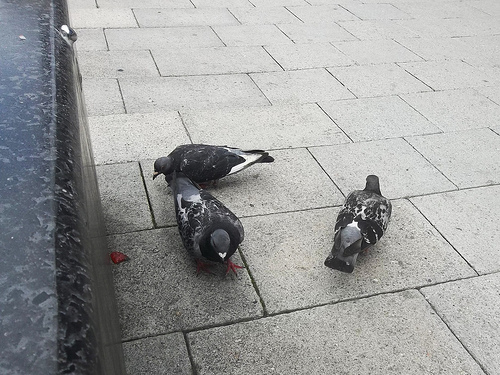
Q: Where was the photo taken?
A: It was taken at the sidewalk.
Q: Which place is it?
A: It is a sidewalk.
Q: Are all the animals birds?
A: No, there are both pigeons and birds.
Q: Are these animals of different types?
A: Yes, they are pigeons and birds.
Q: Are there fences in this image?
A: No, there are no fences.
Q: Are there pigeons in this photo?
A: Yes, there is a pigeon.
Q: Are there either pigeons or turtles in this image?
A: Yes, there is a pigeon.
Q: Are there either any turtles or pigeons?
A: Yes, there is a pigeon.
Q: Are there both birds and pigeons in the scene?
A: Yes, there are both a pigeon and a bird.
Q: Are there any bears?
A: No, there are no bears.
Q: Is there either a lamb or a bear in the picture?
A: No, there are no bears or lambs.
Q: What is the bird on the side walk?
A: The bird is a pigeon.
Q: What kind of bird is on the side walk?
A: The bird is a pigeon.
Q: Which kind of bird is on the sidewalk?
A: The bird is a pigeon.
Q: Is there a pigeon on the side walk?
A: Yes, there is a pigeon on the side walk.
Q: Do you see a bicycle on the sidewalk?
A: No, there is a pigeon on the sidewalk.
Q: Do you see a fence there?
A: No, there are no fences.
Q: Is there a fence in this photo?
A: No, there are no fences.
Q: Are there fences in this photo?
A: No, there are no fences.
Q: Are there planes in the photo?
A: No, there are no planes.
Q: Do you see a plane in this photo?
A: No, there are no airplanes.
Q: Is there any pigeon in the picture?
A: Yes, there is a pigeon.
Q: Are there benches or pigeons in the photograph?
A: Yes, there is a pigeon.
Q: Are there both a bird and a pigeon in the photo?
A: Yes, there are both a pigeon and a bird.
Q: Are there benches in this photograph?
A: No, there are no benches.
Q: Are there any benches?
A: No, there are no benches.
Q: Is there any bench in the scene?
A: No, there are no benches.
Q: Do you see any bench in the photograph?
A: No, there are no benches.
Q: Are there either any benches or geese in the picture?
A: No, there are no benches or geese.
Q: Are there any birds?
A: Yes, there is a bird.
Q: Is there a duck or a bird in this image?
A: Yes, there is a bird.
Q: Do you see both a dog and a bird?
A: No, there is a bird but no dogs.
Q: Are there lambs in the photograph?
A: No, there are no lambs.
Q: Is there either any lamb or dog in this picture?
A: No, there are no lambs or dogs.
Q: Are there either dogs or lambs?
A: No, there are no lambs or dogs.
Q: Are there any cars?
A: No, there are no cars.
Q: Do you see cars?
A: No, there are no cars.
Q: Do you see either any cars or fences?
A: No, there are no cars or fences.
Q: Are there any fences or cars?
A: No, there are no cars or fences.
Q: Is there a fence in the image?
A: No, there are no fences.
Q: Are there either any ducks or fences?
A: No, there are no fences or ducks.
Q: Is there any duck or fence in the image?
A: No, there are no fences or ducks.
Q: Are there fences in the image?
A: No, there are no fences.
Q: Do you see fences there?
A: No, there are no fences.